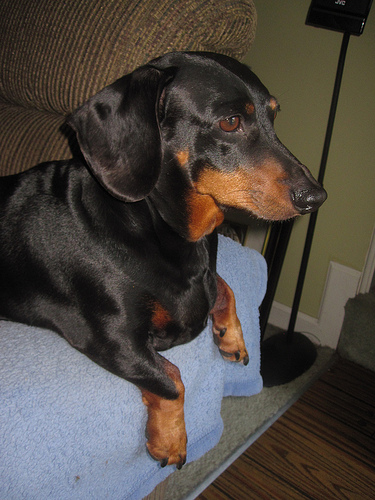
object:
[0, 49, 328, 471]
dog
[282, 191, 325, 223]
mouth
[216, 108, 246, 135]
eyes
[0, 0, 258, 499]
couch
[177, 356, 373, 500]
floor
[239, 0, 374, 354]
wall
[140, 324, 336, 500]
carpet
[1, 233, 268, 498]
blanket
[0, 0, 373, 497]
living room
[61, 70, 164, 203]
ear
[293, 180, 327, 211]
nose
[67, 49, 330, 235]
head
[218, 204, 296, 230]
jaw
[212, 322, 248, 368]
paw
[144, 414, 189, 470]
paw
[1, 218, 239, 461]
couch arm